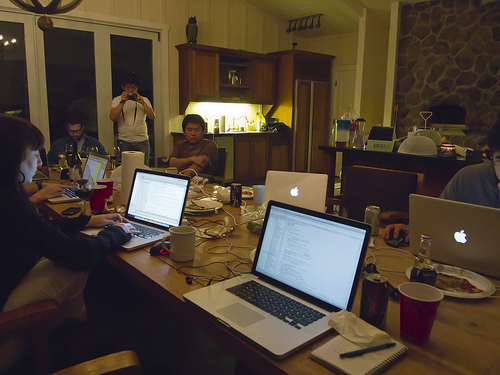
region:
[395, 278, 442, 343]
Red solo cup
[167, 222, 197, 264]
A mug on a table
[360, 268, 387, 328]
A can of soda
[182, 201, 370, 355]
Laptop on a table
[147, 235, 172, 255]
A computer mouse on a table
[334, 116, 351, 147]
A pitcher on a table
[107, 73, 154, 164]
Man holding a camera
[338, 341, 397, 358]
A pen on a pad of paper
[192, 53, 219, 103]
A cabinet door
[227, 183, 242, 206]
A black can of soda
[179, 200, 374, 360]
An open laptop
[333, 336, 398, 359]
A black pen on top of a notebook.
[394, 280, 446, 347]
A red plastic cup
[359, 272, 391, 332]
A black coke can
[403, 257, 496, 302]
A paper plate with food on it.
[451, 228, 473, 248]
A lit up Apple symbol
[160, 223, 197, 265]
A white coffee cup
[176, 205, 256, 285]
A bunch of wires on the table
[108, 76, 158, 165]
A man taking a photo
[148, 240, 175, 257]
A computer mouse with red light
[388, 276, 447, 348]
red plastic cup on table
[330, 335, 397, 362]
blue ink pen on notepad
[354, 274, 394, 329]
black soda can sitting on table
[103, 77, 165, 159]
man holding black camera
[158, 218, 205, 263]
white coffee mug sitting on table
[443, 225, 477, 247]
company logo on top of laptop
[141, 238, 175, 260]
black and red computer mouse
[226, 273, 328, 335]
black keyboard on laptop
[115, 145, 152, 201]
roll of paper towels behind laptop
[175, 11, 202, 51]
statue sitting on shelf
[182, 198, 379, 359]
this is a MacBook pro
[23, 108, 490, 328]
there are a lot of MacBooks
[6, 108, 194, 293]
she is typing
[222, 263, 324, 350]
the keyboard is black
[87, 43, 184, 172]
he is taking a picture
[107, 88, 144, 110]
this is a camera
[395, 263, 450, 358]
a red plastic cup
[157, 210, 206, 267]
this is a white much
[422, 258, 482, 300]
there is pizza on this plate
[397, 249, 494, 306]
this is a paper plate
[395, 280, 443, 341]
red plastic cup on table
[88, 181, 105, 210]
red plastic cup on table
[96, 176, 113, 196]
red plastic cup on table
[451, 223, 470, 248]
white apple on computer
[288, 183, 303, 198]
white apple on computer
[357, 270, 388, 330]
soda can on table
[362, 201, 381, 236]
soda can on table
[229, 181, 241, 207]
soda can on table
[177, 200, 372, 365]
open laptop on table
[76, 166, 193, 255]
open laptop on table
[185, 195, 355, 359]
A open laptop on the table.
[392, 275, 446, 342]
A red cup on the table.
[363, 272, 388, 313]
A can next to the laptop.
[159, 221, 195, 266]
A white mug next to the laptop.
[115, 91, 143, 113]
A man holding a camera in his hands.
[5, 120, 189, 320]
a woman typing on a laptop